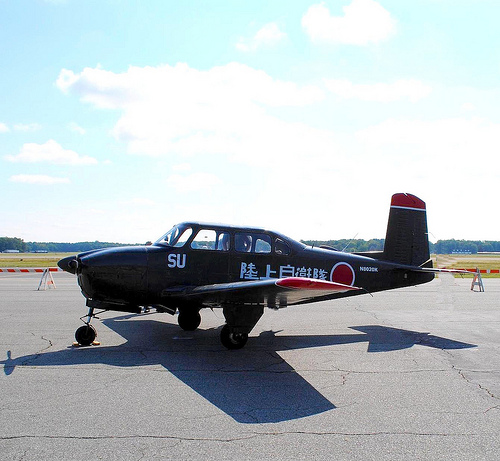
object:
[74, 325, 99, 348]
landing gear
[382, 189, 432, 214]
red tip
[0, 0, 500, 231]
blue sky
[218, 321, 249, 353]
landing gear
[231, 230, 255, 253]
plane window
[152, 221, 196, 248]
plane window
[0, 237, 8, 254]
tree tops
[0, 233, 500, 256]
horizon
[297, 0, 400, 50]
cloud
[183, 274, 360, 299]
wing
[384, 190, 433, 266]
tail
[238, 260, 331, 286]
characters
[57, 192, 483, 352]
plane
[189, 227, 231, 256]
window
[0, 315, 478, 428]
shadow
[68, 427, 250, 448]
cement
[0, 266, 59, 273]
barriers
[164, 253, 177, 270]
letters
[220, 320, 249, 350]
wheel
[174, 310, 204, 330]
wheel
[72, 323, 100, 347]
wheel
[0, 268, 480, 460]
tarmac